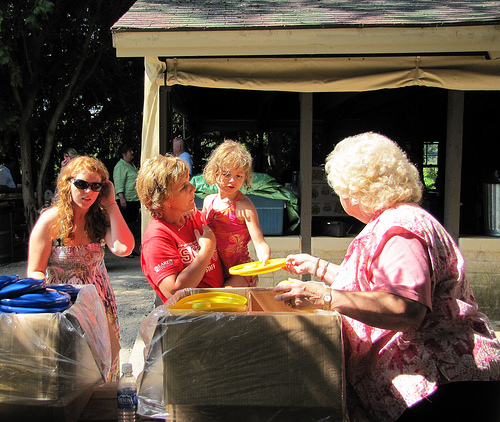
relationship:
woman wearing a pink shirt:
[272, 130, 499, 420] [333, 205, 499, 421]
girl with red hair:
[23, 152, 129, 382] [53, 153, 110, 247]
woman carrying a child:
[133, 155, 227, 305] [198, 138, 275, 288]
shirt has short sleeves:
[138, 213, 228, 305] [143, 237, 186, 288]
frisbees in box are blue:
[0, 274, 79, 322] [25, 295, 45, 305]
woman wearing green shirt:
[110, 141, 143, 261] [111, 159, 143, 212]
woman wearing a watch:
[272, 130, 499, 420] [319, 286, 335, 311]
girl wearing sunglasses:
[23, 152, 129, 382] [67, 179, 105, 196]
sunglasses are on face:
[67, 179, 105, 196] [67, 168, 100, 212]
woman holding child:
[133, 155, 227, 305] [198, 138, 275, 288]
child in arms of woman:
[198, 138, 275, 288] [133, 155, 227, 305]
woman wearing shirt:
[272, 130, 499, 420] [333, 205, 499, 421]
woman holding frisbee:
[272, 130, 499, 420] [228, 254, 292, 278]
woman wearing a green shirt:
[110, 141, 143, 261] [111, 159, 143, 212]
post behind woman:
[442, 85, 466, 248] [272, 130, 499, 420]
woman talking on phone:
[55, 147, 81, 172] [63, 156, 72, 165]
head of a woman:
[315, 129, 430, 225] [272, 130, 499, 420]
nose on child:
[229, 177, 237, 185] [198, 138, 275, 288]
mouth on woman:
[187, 196, 198, 205] [133, 155, 227, 305]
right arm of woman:
[315, 253, 349, 285] [272, 130, 499, 420]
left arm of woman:
[324, 256, 434, 337] [272, 130, 499, 420]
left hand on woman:
[269, 276, 323, 315] [272, 130, 499, 420]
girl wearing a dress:
[23, 152, 129, 382] [49, 239, 121, 381]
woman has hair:
[133, 155, 227, 305] [135, 152, 189, 221]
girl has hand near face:
[23, 152, 129, 382] [67, 168, 100, 212]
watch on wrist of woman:
[319, 286, 335, 311] [272, 130, 499, 420]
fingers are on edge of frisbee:
[281, 256, 296, 276] [228, 254, 292, 278]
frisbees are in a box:
[0, 274, 79, 322] [1, 282, 110, 421]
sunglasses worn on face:
[67, 179, 105, 196] [67, 168, 100, 212]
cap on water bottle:
[121, 361, 134, 374] [115, 363, 142, 421]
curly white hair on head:
[325, 133, 425, 212] [315, 129, 430, 225]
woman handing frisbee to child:
[272, 130, 499, 420] [198, 138, 275, 288]